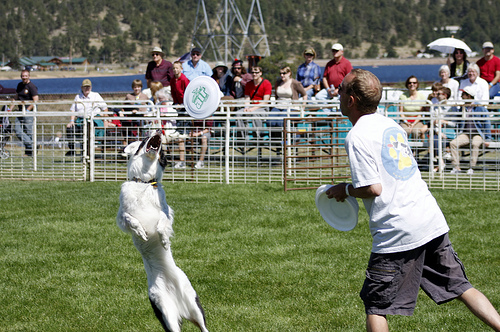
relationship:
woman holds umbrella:
[449, 47, 470, 79] [424, 35, 474, 54]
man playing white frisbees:
[320, 65, 497, 330] [314, 184, 361, 232]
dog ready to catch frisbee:
[120, 133, 212, 331] [181, 72, 226, 122]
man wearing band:
[320, 65, 497, 330] [345, 181, 351, 198]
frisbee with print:
[181, 72, 226, 122] [192, 85, 209, 108]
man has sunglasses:
[320, 65, 497, 330] [336, 80, 356, 97]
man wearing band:
[320, 65, 497, 330] [345, 181, 351, 196]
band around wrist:
[345, 181, 351, 196] [343, 183, 357, 200]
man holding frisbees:
[324, 66, 500, 331] [316, 181, 361, 233]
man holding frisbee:
[324, 66, 500, 331] [318, 188, 357, 236]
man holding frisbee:
[324, 66, 500, 331] [317, 181, 358, 211]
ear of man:
[343, 91, 363, 113] [320, 65, 497, 330]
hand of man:
[325, 181, 379, 200] [320, 65, 497, 330]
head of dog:
[124, 130, 170, 182] [120, 133, 212, 331]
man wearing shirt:
[320, 65, 497, 330] [343, 112, 450, 254]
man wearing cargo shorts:
[320, 65, 497, 330] [358, 234, 473, 317]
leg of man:
[358, 257, 400, 329] [320, 65, 497, 330]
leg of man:
[431, 250, 498, 328] [320, 65, 497, 330]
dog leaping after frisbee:
[120, 133, 212, 331] [183, 75, 226, 122]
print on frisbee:
[192, 85, 206, 108] [184, 75, 221, 117]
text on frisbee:
[189, 87, 208, 107] [181, 74, 221, 118]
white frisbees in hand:
[309, 177, 361, 231] [324, 181, 350, 201]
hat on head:
[75, 75, 93, 91] [77, 75, 97, 97]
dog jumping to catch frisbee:
[96, 109, 215, 330] [171, 59, 226, 123]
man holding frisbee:
[324, 66, 500, 331] [279, 177, 355, 235]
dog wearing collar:
[120, 133, 212, 331] [129, 175, 164, 189]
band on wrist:
[345, 181, 351, 198] [337, 182, 359, 203]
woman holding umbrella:
[449, 49, 470, 79] [427, 37, 473, 57]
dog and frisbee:
[120, 133, 212, 331] [181, 74, 223, 121]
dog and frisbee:
[120, 133, 212, 331] [311, 183, 358, 231]